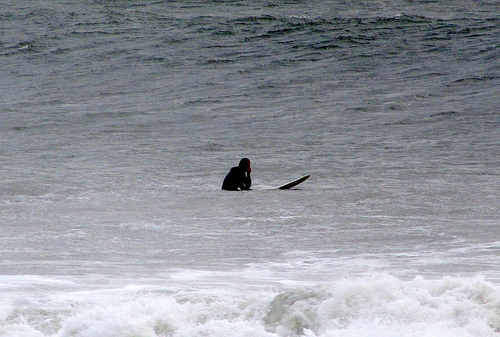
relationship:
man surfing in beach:
[222, 158, 252, 191] [7, 4, 497, 334]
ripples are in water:
[344, 94, 479, 186] [1, 3, 498, 334]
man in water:
[222, 158, 252, 191] [266, 52, 463, 137]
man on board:
[222, 158, 252, 191] [279, 174, 311, 189]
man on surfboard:
[222, 158, 252, 191] [252, 158, 313, 200]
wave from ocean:
[93, 259, 475, 335] [28, 33, 488, 335]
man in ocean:
[219, 156, 254, 191] [2, 1, 499, 333]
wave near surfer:
[0, 0, 500, 337] [204, 141, 334, 199]